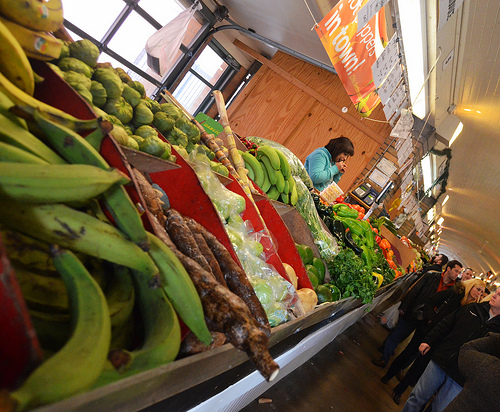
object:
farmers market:
[1, 0, 500, 412]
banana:
[143, 231, 216, 344]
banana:
[114, 280, 184, 376]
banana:
[8, 245, 114, 412]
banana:
[6, 204, 160, 289]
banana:
[0, 158, 132, 206]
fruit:
[54, 35, 233, 179]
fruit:
[230, 144, 297, 206]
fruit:
[294, 241, 344, 306]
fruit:
[0, 1, 212, 410]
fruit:
[190, 164, 296, 326]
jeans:
[402, 359, 471, 412]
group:
[370, 249, 500, 412]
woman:
[302, 135, 356, 192]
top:
[300, 149, 342, 188]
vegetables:
[329, 249, 377, 312]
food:
[0, 0, 434, 412]